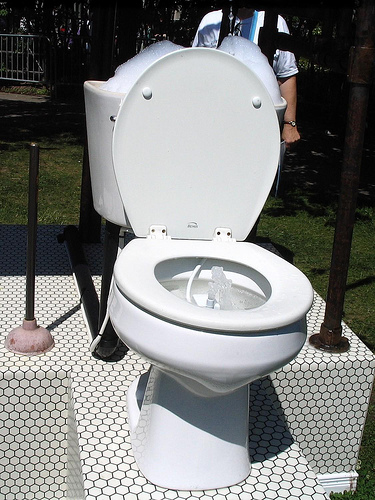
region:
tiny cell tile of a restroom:
[21, 400, 41, 413]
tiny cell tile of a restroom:
[25, 438, 60, 461]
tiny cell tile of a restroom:
[94, 463, 125, 491]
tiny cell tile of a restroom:
[278, 436, 296, 461]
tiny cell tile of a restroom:
[290, 402, 311, 423]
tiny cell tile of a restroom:
[320, 377, 333, 400]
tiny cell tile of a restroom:
[327, 363, 347, 379]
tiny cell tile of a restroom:
[58, 296, 70, 321]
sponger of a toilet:
[1, 308, 67, 358]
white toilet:
[83, 29, 321, 487]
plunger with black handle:
[9, 144, 56, 352]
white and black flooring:
[0, 273, 363, 499]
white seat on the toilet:
[114, 229, 313, 332]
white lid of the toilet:
[120, 58, 274, 235]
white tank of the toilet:
[84, 80, 284, 221]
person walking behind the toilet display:
[190, 5, 308, 215]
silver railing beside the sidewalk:
[2, 30, 51, 88]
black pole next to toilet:
[315, 28, 368, 356]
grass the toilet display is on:
[10, 144, 374, 499]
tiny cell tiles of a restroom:
[30, 382, 45, 394]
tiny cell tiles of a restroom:
[24, 398, 50, 418]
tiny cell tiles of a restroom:
[94, 453, 132, 489]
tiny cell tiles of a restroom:
[267, 442, 294, 461]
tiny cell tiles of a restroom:
[325, 383, 340, 405]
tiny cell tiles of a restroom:
[83, 367, 109, 393]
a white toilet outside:
[68, 103, 307, 328]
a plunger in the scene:
[9, 139, 62, 355]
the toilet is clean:
[112, 242, 311, 463]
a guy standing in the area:
[204, 3, 314, 142]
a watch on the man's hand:
[278, 109, 313, 157]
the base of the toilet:
[121, 378, 280, 499]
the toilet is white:
[103, 238, 308, 482]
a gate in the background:
[0, 26, 56, 88]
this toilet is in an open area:
[27, 60, 300, 318]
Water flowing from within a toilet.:
[204, 261, 246, 310]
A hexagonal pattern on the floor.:
[88, 404, 113, 466]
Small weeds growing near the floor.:
[334, 435, 374, 496]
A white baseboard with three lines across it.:
[316, 471, 361, 495]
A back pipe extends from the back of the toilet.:
[58, 221, 118, 353]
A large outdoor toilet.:
[57, 49, 328, 494]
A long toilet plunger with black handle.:
[7, 136, 61, 356]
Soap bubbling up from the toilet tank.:
[118, 30, 279, 117]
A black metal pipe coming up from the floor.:
[316, 11, 372, 359]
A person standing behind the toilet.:
[192, 2, 300, 199]